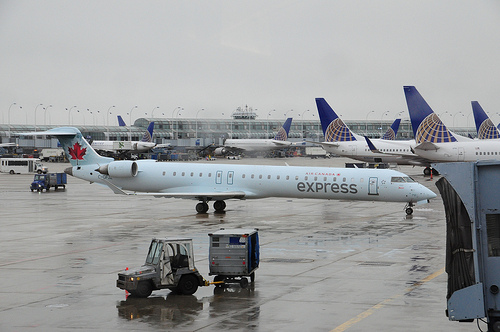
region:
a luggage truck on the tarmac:
[119, 222, 261, 302]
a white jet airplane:
[27, 121, 432, 207]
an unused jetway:
[429, 153, 498, 316]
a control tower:
[229, 104, 262, 117]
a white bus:
[0, 159, 47, 173]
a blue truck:
[29, 172, 76, 193]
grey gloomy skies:
[0, 1, 498, 116]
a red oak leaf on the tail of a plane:
[60, 136, 86, 161]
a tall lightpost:
[28, 99, 44, 122]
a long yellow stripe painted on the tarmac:
[329, 264, 443, 327]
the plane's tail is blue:
[312, 92, 336, 120]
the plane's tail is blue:
[302, 104, 347, 138]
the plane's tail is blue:
[322, 97, 350, 142]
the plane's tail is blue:
[305, 77, 372, 175]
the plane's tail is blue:
[313, 87, 343, 154]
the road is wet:
[295, 264, 367, 295]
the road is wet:
[309, 227, 366, 287]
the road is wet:
[325, 288, 340, 299]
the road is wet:
[315, 260, 375, 314]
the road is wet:
[322, 280, 372, 310]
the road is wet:
[323, 281, 354, 305]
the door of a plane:
[364, 174, 381, 198]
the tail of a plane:
[8, 117, 120, 166]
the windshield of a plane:
[389, 175, 416, 182]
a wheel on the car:
[129, 274, 153, 298]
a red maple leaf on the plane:
[61, 135, 91, 162]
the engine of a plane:
[91, 157, 143, 180]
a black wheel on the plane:
[192, 198, 211, 215]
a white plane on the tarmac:
[8, 122, 440, 223]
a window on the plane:
[281, 169, 292, 182]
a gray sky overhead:
[1, 0, 498, 127]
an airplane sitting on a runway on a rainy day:
[23, 122, 428, 222]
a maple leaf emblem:
[64, 140, 89, 165]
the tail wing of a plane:
[17, 123, 110, 160]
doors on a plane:
[214, 170, 235, 185]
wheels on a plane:
[195, 197, 234, 217]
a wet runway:
[308, 218, 383, 319]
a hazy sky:
[41, 17, 419, 74]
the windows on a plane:
[240, 171, 348, 183]